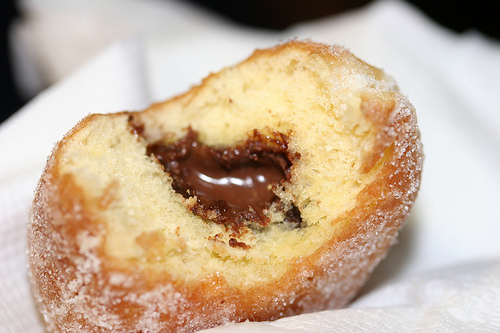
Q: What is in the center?
A: Chocolate.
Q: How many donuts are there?
A: One.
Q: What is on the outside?
A: Powdered sugar.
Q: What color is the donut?
A: Brown.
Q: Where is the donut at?
A: A napkin.